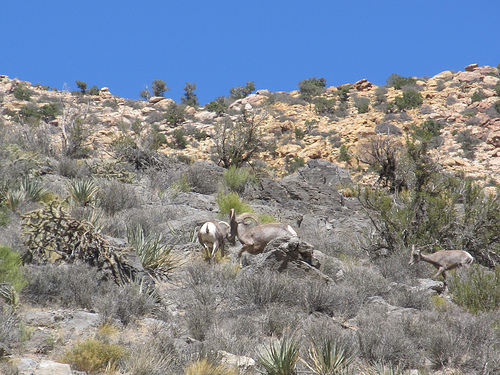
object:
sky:
[53, 65, 85, 78]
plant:
[301, 339, 351, 374]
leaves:
[258, 330, 304, 374]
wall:
[457, 122, 482, 157]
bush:
[218, 164, 261, 193]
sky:
[230, 55, 271, 72]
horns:
[238, 211, 260, 226]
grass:
[171, 169, 199, 199]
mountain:
[0, 62, 499, 188]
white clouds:
[289, 32, 320, 65]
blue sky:
[0, 0, 32, 17]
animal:
[407, 242, 474, 285]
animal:
[197, 219, 233, 266]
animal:
[226, 207, 299, 269]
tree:
[13, 193, 144, 287]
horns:
[229, 207, 237, 223]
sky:
[0, 35, 39, 73]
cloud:
[224, 24, 295, 89]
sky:
[469, 53, 497, 63]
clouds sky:
[457, 0, 499, 23]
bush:
[174, 279, 226, 341]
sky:
[183, 0, 226, 13]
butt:
[199, 221, 216, 242]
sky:
[55, 29, 98, 59]